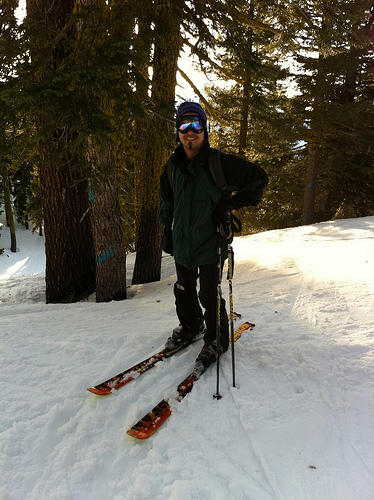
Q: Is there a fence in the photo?
A: No, there are no fences.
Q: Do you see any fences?
A: No, there are no fences.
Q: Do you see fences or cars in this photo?
A: No, there are no fences or cars.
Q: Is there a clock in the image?
A: No, there are no clocks.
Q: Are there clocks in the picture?
A: No, there are no clocks.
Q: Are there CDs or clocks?
A: No, there are no clocks or cds.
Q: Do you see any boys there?
A: No, there are no boys.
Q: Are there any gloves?
A: Yes, there are gloves.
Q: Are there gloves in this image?
A: Yes, there are gloves.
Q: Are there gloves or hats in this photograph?
A: Yes, there are gloves.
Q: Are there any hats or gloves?
A: Yes, there are gloves.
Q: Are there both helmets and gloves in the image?
A: No, there are gloves but no helmets.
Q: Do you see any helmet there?
A: No, there are no helmets.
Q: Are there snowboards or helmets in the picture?
A: No, there are no helmets or snowboards.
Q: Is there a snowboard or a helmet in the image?
A: No, there are no helmets or snowboards.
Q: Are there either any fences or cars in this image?
A: No, there are no fences or cars.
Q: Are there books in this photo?
A: No, there are no books.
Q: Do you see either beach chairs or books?
A: No, there are no books or beach chairs.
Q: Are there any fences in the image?
A: No, there are no fences.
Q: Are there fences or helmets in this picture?
A: No, there are no fences or helmets.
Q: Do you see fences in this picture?
A: No, there are no fences.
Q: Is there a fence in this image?
A: No, there are no fences.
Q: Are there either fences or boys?
A: No, there are no fences or boys.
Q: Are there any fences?
A: No, there are no fences.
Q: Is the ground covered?
A: Yes, the ground is covered.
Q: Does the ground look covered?
A: Yes, the ground is covered.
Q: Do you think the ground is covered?
A: Yes, the ground is covered.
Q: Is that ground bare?
A: No, the ground is covered.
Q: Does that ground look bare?
A: No, the ground is covered.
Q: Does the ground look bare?
A: No, the ground is covered.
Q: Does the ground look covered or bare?
A: The ground is covered.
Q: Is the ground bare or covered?
A: The ground is covered.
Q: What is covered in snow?
A: The ground is covered in snow.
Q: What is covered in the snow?
A: The ground is covered in snow.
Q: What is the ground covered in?
A: The ground is covered in snow.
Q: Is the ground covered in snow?
A: Yes, the ground is covered in snow.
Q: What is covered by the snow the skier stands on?
A: The ground is covered by the snow.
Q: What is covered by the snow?
A: The ground is covered by the snow.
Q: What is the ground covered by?
A: The ground is covered by the snow.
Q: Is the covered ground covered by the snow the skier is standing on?
A: Yes, the ground is covered by the snow.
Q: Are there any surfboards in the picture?
A: No, there are no surfboards.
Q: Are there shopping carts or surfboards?
A: No, there are no surfboards or shopping carts.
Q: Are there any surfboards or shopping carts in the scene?
A: No, there are no surfboards or shopping carts.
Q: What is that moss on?
A: The moss is on the tree.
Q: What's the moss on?
A: The moss is on the tree.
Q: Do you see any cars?
A: No, there are no cars.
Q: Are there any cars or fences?
A: No, there are no cars or fences.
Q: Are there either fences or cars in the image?
A: No, there are no cars or fences.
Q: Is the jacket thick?
A: Yes, the jacket is thick.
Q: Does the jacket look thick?
A: Yes, the jacket is thick.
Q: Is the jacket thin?
A: No, the jacket is thick.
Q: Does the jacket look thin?
A: No, the jacket is thick.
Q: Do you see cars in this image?
A: No, there are no cars.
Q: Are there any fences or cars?
A: No, there are no cars or fences.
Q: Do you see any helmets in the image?
A: No, there are no helmets.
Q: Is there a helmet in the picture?
A: No, there are no helmets.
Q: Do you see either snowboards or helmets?
A: No, there are no helmets or snowboards.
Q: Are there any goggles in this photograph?
A: Yes, there are goggles.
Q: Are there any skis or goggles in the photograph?
A: Yes, there are goggles.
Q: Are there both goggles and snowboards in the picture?
A: No, there are goggles but no snowboards.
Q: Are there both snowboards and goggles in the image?
A: No, there are goggles but no snowboards.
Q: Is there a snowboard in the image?
A: No, there are no snowboards.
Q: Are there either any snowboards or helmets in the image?
A: No, there are no snowboards or helmets.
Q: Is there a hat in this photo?
A: Yes, there is a hat.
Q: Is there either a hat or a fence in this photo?
A: Yes, there is a hat.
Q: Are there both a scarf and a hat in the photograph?
A: No, there is a hat but no scarves.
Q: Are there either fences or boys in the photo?
A: No, there are no fences or boys.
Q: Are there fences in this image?
A: No, there are no fences.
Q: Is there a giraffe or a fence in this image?
A: No, there are no fences or giraffes.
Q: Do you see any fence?
A: No, there are no fences.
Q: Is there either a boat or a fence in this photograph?
A: No, there are no fences or boats.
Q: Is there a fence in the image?
A: No, there are no fences.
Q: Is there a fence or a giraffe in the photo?
A: No, there are no fences or giraffes.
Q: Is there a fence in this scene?
A: No, there are no fences.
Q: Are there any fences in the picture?
A: No, there are no fences.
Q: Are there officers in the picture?
A: No, there are no officers.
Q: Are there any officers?
A: No, there are no officers.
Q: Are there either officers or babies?
A: No, there are no officers or babies.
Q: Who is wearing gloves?
A: The skier is wearing gloves.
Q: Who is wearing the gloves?
A: The skier is wearing gloves.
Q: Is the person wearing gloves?
A: Yes, the skier is wearing gloves.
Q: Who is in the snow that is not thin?
A: The skier is in the snow.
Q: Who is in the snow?
A: The skier is in the snow.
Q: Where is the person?
A: The skier is in the snow.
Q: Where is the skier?
A: The skier is in the snow.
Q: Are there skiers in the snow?
A: Yes, there is a skier in the snow.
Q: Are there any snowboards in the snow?
A: No, there is a skier in the snow.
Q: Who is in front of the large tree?
A: The skier is in front of the tree.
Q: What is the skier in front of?
A: The skier is in front of the tree.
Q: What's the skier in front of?
A: The skier is in front of the tree.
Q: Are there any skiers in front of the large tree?
A: Yes, there is a skier in front of the tree.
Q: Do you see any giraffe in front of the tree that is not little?
A: No, there is a skier in front of the tree.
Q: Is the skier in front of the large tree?
A: Yes, the skier is in front of the tree.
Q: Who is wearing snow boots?
A: The skier is wearing snow boots.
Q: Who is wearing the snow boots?
A: The skier is wearing snow boots.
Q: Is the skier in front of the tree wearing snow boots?
A: Yes, the skier is wearing snow boots.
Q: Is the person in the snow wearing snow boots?
A: Yes, the skier is wearing snow boots.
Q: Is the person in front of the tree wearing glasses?
A: No, the skier is wearing snow boots.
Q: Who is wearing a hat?
A: The skier is wearing a hat.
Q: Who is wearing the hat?
A: The skier is wearing a hat.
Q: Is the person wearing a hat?
A: Yes, the skier is wearing a hat.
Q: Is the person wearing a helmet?
A: No, the skier is wearing a hat.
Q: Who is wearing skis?
A: The skier is wearing skis.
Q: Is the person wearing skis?
A: Yes, the skier is wearing skis.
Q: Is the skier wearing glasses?
A: No, the skier is wearing skis.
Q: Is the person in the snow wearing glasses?
A: No, the skier is wearing skis.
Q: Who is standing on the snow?
A: The skier is standing on the snow.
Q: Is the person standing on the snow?
A: Yes, the skier is standing on the snow.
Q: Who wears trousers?
A: The skier wears trousers.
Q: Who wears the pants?
A: The skier wears trousers.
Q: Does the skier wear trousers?
A: Yes, the skier wears trousers.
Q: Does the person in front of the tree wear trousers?
A: Yes, the skier wears trousers.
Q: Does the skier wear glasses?
A: No, the skier wears trousers.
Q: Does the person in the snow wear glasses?
A: No, the skier wears trousers.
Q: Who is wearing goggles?
A: The skier is wearing goggles.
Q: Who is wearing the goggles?
A: The skier is wearing goggles.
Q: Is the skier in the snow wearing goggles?
A: Yes, the skier is wearing goggles.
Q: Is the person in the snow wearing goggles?
A: Yes, the skier is wearing goggles.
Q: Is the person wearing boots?
A: No, the skier is wearing goggles.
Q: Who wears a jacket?
A: The skier wears a jacket.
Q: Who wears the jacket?
A: The skier wears a jacket.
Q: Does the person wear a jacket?
A: Yes, the skier wears a jacket.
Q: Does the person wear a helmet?
A: No, the skier wears a jacket.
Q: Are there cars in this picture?
A: No, there are no cars.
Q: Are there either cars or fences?
A: No, there are no cars or fences.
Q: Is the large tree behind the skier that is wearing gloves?
A: Yes, the tree is behind the skier.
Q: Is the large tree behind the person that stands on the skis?
A: Yes, the tree is behind the skier.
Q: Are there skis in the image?
A: Yes, there are skis.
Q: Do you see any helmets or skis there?
A: Yes, there are skis.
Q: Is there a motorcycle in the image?
A: No, there are no motorcycles.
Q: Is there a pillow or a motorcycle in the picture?
A: No, there are no motorcycles or pillows.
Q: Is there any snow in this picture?
A: Yes, there is snow.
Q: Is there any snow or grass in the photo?
A: Yes, there is snow.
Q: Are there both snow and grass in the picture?
A: No, there is snow but no grass.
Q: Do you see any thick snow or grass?
A: Yes, there is thick snow.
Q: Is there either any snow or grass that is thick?
A: Yes, the snow is thick.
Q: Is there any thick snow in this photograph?
A: Yes, there is thick snow.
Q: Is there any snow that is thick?
A: Yes, there is snow that is thick.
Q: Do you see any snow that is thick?
A: Yes, there is snow that is thick.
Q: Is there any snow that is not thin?
A: Yes, there is thick snow.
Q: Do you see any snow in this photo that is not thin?
A: Yes, there is thick snow.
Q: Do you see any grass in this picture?
A: No, there is no grass.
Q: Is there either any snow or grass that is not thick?
A: No, there is snow but it is thick.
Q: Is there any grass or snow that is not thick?
A: No, there is snow but it is thick.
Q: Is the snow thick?
A: Yes, the snow is thick.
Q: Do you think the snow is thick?
A: Yes, the snow is thick.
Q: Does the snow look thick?
A: Yes, the snow is thick.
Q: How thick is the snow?
A: The snow is thick.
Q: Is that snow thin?
A: No, the snow is thick.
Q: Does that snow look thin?
A: No, the snow is thick.